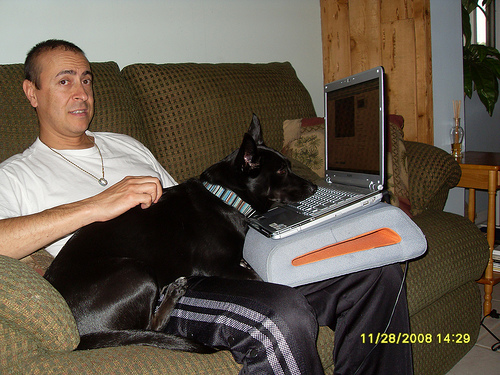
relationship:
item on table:
[445, 94, 481, 174] [440, 123, 499, 324]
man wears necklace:
[0, 37, 416, 373] [44, 131, 153, 220]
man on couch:
[0, 37, 416, 373] [0, 60, 490, 374]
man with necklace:
[0, 37, 416, 373] [34, 133, 109, 187]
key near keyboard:
[333, 200, 336, 204] [295, 187, 362, 213]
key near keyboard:
[308, 196, 313, 203] [295, 187, 362, 213]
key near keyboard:
[349, 194, 354, 199] [295, 187, 362, 213]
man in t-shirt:
[0, 37, 416, 373] [2, 131, 180, 258]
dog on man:
[42, 108, 320, 355] [0, 37, 416, 373]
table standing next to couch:
[459, 150, 499, 316] [154, 77, 222, 139]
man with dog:
[0, 37, 416, 373] [47, 111, 312, 333]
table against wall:
[459, 150, 497, 227] [432, 0, 495, 145]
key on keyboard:
[311, 187, 332, 201] [291, 182, 358, 215]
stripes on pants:
[177, 295, 305, 375] [158, 263, 415, 373]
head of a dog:
[229, 110, 331, 222] [141, 55, 342, 273]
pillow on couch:
[0, 256, 83, 353] [0, 60, 490, 374]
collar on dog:
[187, 174, 264, 213] [13, 114, 340, 361]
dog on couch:
[42, 108, 320, 355] [0, 60, 490, 374]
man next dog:
[0, 37, 416, 373] [27, 108, 328, 335]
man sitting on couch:
[0, 37, 416, 373] [25, 30, 479, 367]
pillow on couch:
[279, 110, 413, 220] [0, 62, 496, 374]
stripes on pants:
[148, 285, 303, 373] [137, 232, 419, 372]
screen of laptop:
[323, 77, 379, 173] [244, 65, 389, 235]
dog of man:
[38, 110, 320, 314] [0, 37, 416, 373]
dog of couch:
[42, 108, 320, 355] [0, 60, 490, 374]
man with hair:
[13, 20, 165, 240] [15, 33, 89, 81]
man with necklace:
[13, 20, 165, 240] [26, 121, 114, 188]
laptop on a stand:
[230, 60, 391, 241] [220, 194, 434, 286]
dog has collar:
[42, 108, 320, 355] [203, 179, 256, 221]